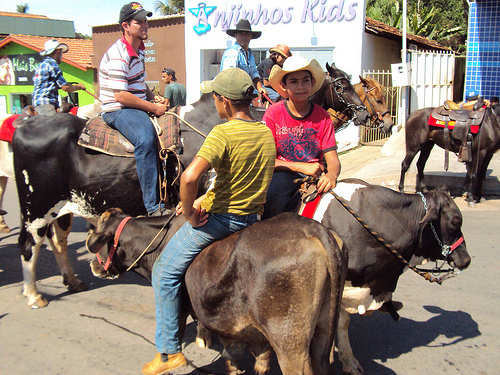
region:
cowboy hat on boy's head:
[270, 52, 328, 101]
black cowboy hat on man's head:
[224, 21, 264, 38]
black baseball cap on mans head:
[116, 4, 152, 20]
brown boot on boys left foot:
[141, 350, 185, 371]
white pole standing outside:
[399, 7, 408, 142]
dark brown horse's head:
[328, 63, 365, 121]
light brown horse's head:
[356, 77, 399, 127]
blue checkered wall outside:
[468, 0, 498, 93]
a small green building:
[2, 36, 33, 98]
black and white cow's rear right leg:
[19, 218, 49, 305]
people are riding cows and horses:
[1, 7, 499, 374]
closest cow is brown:
[87, 208, 347, 373]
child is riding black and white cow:
[211, 169, 471, 372]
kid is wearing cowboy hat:
[270, 54, 322, 97]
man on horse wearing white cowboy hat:
[39, 38, 66, 56]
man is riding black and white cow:
[7, 2, 269, 308]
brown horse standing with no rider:
[396, 89, 499, 209]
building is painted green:
[1, 44, 94, 117]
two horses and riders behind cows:
[221, 21, 394, 134]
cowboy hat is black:
[225, 18, 263, 39]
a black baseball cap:
[115, 0, 153, 21]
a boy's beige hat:
[265, 55, 328, 94]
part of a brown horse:
[397, 102, 497, 211]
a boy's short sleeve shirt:
[194, 118, 279, 218]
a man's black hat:
[225, 15, 265, 40]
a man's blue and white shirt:
[30, 58, 67, 106]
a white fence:
[362, 67, 397, 139]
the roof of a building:
[15, 33, 91, 64]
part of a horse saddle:
[77, 110, 182, 158]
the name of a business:
[212, 1, 359, 32]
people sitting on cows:
[12, 80, 459, 303]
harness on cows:
[302, 143, 468, 281]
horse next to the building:
[385, 82, 497, 198]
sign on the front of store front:
[181, 7, 371, 55]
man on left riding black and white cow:
[12, 70, 250, 272]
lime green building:
[0, 21, 96, 111]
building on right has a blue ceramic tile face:
[466, 11, 497, 151]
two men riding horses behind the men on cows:
[202, 16, 399, 147]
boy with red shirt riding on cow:
[243, 45, 471, 307]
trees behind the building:
[354, 0, 469, 47]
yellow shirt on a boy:
[196, 121, 276, 223]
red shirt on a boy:
[260, 92, 340, 197]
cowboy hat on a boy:
[267, 52, 334, 109]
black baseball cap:
[107, 4, 161, 28]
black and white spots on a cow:
[15, 136, 64, 246]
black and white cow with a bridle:
[324, 186, 478, 313]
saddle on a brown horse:
[432, 86, 490, 175]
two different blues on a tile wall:
[462, 13, 497, 88]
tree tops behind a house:
[410, 3, 447, 34]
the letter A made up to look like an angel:
[189, 3, 214, 35]